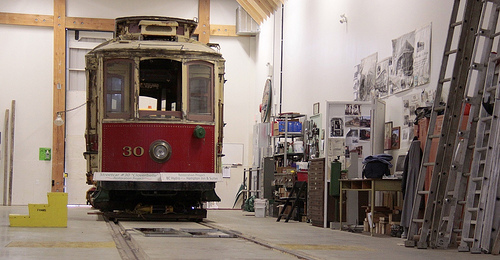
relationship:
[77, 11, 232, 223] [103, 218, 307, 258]
train on tracks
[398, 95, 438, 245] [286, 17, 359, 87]
ladder stacked against wall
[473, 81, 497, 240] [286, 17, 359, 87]
ladder stacked against wall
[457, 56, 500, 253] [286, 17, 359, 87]
ladder stacked against wall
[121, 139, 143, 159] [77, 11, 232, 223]
30 on train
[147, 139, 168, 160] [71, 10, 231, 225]
headlight on trolley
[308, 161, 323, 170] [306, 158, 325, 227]
drawer in tool cabinet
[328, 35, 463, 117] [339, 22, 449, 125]
posters on wall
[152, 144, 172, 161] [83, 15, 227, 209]
headlight on train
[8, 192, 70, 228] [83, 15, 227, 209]
yellow steps are by train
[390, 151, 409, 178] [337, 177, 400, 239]
computer on a workbench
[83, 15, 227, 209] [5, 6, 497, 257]
train in garage